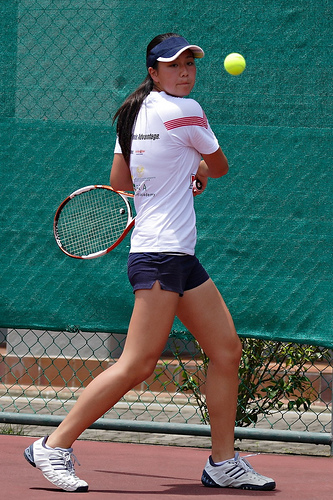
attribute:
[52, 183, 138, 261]
racket — red, white, black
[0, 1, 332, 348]
cover — green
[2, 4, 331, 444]
fence — silver, metal, chain-link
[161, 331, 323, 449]
plant — green, leafy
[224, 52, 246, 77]
tennis ball — yellow, small, globular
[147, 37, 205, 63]
visor — blue, white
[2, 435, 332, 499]
court — red, hard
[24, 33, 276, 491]
woman — amateur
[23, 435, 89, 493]
shoe — white, black, gray, dark blue, blue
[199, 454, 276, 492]
shoe — white, black, gray, dark blue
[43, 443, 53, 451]
sock — white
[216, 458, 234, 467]
sock — white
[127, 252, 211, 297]
shorts — dark blue, blue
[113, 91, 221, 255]
tee shirt — white